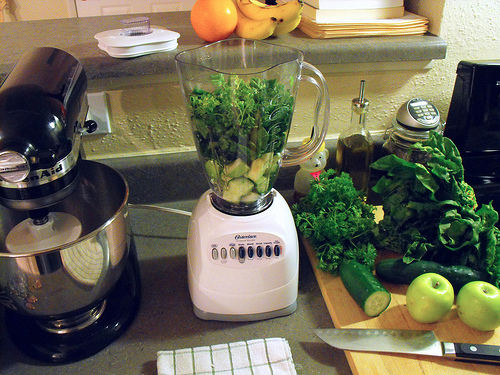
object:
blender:
[175, 33, 335, 327]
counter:
[3, 129, 497, 371]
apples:
[402, 269, 457, 326]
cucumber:
[340, 256, 395, 320]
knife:
[309, 321, 499, 369]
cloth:
[153, 335, 296, 374]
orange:
[190, 2, 237, 44]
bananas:
[234, 0, 276, 40]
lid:
[96, 15, 186, 64]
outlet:
[81, 90, 123, 139]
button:
[273, 244, 283, 259]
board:
[296, 205, 499, 374]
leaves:
[294, 161, 395, 275]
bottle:
[335, 78, 375, 201]